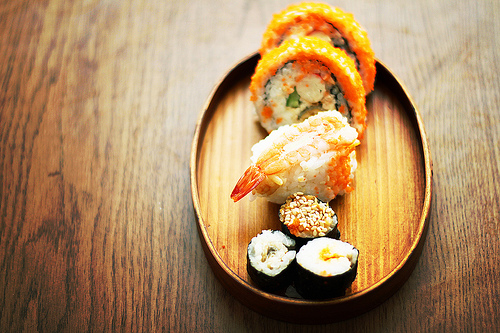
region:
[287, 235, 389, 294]
a piece of food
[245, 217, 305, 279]
a piece of food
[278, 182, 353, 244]
a piece of food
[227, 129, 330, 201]
a piece of food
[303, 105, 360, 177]
a piece of food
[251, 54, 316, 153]
a piece of food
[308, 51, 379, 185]
a piece of food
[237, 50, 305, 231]
a piece of food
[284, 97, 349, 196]
a piece of food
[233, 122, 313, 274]
a piece of food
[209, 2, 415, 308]
Sushi on a wooden plate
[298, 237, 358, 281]
A small piece of sushi at the end of the plate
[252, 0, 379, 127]
Two bigger pieces of sushi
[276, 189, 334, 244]
A piece of sushi with rice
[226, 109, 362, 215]
A bigger piece of food in the middle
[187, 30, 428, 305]
The oval shaped plate made of wood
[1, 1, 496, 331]
The wooden table where the food sits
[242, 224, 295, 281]
Another small piece of sushi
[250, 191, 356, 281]
Three small pieces of sushi together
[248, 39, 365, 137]
One big and orange piece of sushi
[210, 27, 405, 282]
food in the photo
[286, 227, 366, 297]
small piece of food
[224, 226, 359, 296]
two round pieces of food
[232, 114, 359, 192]
large piece of food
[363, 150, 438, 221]
brown bowl in photo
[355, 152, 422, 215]
plate holding some food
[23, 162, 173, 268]
lines on the table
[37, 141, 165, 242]
brown table in photo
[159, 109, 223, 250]
edge of the bowl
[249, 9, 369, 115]
two orange pieces of food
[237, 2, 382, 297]
maki on the bamboo plate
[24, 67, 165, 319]
a brown wooden table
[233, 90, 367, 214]
a piece of food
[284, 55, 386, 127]
a piece of food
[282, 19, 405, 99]
a piece of food